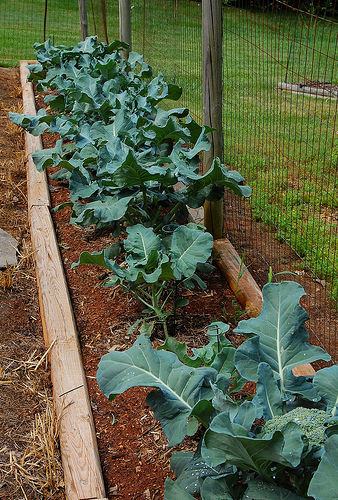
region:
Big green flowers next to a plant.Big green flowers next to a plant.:
[27, 379, 57, 444]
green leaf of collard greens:
[115, 348, 196, 420]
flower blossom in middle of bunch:
[272, 412, 328, 436]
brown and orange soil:
[116, 453, 130, 468]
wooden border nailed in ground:
[53, 429, 88, 472]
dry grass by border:
[12, 440, 52, 481]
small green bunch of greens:
[179, 342, 246, 382]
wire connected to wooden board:
[276, 198, 333, 248]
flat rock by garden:
[4, 217, 27, 290]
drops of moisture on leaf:
[187, 450, 200, 472]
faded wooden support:
[205, 51, 237, 89]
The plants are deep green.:
[9, 35, 336, 499]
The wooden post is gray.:
[199, 0, 224, 239]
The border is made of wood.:
[17, 57, 316, 498]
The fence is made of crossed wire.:
[0, 0, 337, 381]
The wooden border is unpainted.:
[17, 58, 322, 499]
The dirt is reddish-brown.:
[27, 61, 259, 499]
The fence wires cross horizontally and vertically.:
[7, 5, 336, 389]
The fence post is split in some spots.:
[199, 0, 225, 241]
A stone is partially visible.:
[0, 225, 21, 266]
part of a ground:
[112, 420, 133, 439]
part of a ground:
[133, 444, 154, 467]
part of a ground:
[132, 432, 161, 464]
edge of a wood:
[79, 457, 112, 485]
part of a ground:
[129, 446, 153, 479]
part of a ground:
[134, 422, 157, 444]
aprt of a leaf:
[183, 409, 207, 441]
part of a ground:
[134, 450, 160, 487]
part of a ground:
[126, 403, 152, 438]